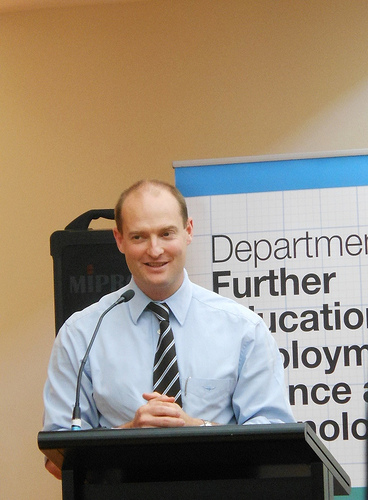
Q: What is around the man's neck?
A: A tie.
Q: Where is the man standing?
A: At a podium.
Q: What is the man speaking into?
A: A microphone.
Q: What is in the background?
A: A sign.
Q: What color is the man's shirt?
A: Light blue.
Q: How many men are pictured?
A: One.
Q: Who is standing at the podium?
A: The man.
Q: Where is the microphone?
A: On the podium.